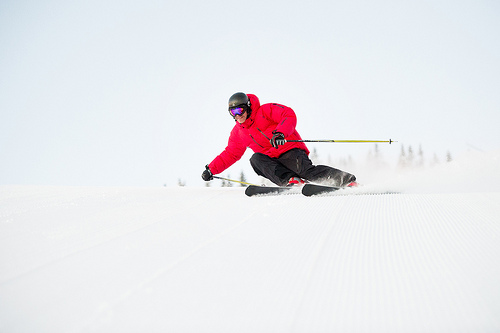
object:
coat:
[199, 91, 310, 176]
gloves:
[269, 132, 287, 150]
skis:
[244, 177, 306, 196]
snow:
[138, 196, 308, 286]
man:
[199, 91, 355, 190]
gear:
[244, 181, 359, 197]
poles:
[212, 176, 265, 188]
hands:
[266, 103, 296, 137]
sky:
[404, 77, 487, 119]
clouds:
[124, 47, 184, 70]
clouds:
[133, 124, 184, 140]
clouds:
[113, 79, 142, 99]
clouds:
[27, 58, 67, 104]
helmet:
[228, 92, 252, 119]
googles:
[229, 108, 245, 117]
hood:
[236, 121, 254, 130]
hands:
[201, 132, 250, 181]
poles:
[283, 139, 399, 145]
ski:
[301, 181, 357, 197]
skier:
[201, 91, 364, 197]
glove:
[201, 169, 213, 181]